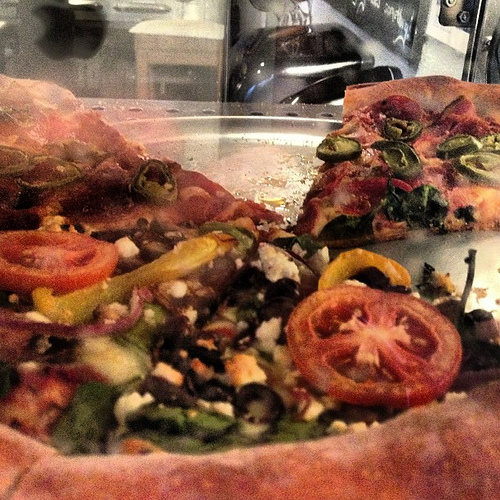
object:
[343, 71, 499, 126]
crust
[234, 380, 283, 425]
vegetable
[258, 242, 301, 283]
cheese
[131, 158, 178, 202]
jalapeno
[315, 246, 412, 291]
vegetable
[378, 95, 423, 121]
pepperoni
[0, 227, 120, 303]
tomato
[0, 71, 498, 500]
pizza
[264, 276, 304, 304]
olive slice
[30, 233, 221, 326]
pepper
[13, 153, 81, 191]
pepper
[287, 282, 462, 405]
tomato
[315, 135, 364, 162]
chili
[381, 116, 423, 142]
chili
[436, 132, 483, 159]
chili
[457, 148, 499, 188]
chili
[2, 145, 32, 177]
chili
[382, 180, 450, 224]
spinach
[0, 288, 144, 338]
onion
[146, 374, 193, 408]
olive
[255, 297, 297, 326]
olive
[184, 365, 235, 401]
olive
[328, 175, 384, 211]
meat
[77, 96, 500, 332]
plate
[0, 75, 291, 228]
slice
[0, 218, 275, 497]
slice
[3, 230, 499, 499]
slice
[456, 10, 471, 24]
nut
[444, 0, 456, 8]
nut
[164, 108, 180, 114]
spot